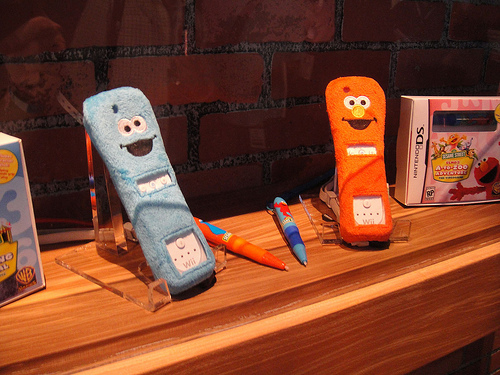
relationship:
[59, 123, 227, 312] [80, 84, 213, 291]
stand for wii controller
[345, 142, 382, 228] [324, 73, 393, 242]
wii controller has orange cover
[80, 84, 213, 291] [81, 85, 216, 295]
wii controller has blue cover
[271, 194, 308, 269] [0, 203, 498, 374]
stylus pen on wooden shelf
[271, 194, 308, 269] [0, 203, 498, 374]
stylus pen sits on top of wooden shelf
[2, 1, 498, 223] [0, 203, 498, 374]
brick wall behind wooden shelf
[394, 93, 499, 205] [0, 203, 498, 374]
ds game on wooden shelf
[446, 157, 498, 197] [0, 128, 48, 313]
elmo on game box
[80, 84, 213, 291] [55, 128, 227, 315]
wii controller leaning against plastic stand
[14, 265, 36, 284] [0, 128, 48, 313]
warner brothers logo on game box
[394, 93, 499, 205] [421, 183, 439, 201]
ds game has rp logo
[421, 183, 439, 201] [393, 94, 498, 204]
rp logo on box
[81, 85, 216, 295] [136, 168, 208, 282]
blue cover on controller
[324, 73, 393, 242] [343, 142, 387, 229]
orange cover on controller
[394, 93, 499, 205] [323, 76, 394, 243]
ds game near wii controller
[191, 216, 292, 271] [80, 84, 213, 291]
orange pen near wii controller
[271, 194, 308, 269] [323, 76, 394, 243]
stylus pen near wii controller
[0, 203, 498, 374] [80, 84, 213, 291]
wooden shelf holding wii controller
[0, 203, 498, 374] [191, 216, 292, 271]
wooden shelf holding orange pen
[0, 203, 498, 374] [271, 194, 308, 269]
wooden shelf holding stylus pen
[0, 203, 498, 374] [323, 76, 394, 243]
wooden shelf holding wii controller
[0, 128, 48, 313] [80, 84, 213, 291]
game box near wii controller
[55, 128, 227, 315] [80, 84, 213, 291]
plastic stand for wii controller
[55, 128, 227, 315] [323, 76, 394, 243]
plastic stand for wii controller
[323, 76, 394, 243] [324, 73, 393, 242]
wii controller with orange cover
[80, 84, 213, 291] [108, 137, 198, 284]
wii controller with cover